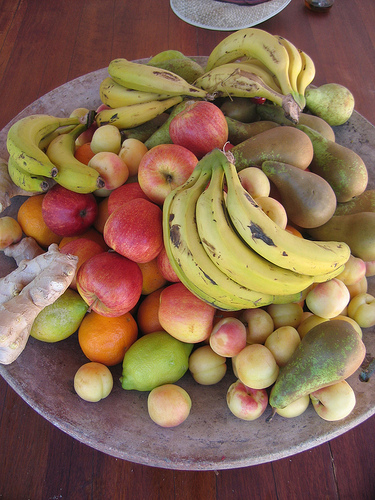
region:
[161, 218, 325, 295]
the bananass are yellow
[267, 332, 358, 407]
the pears is green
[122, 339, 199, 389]
the lemon is green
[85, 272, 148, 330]
the apple is red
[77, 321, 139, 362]
the orange is orange in color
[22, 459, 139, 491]
the table is wooden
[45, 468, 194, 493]
the table is brown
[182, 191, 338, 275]
the bananas are ripe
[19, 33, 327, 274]
there are 4 banches of bananas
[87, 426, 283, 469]
the trey is grey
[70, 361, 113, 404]
a pale yellow peach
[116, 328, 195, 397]
a pale green lime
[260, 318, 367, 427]
a green and brown mottled pear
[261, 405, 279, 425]
the brown stem of a pear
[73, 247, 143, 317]
a ripe red apple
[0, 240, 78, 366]
a tan ginger root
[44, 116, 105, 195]
a yellow ripe banana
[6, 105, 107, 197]
a bunch of bananas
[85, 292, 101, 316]
the stem of an apple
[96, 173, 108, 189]
the end of a banan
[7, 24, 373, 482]
Fruits in a bowl.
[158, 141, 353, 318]
Handle of bananas on top.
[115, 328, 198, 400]
Lemon is green.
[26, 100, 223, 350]
Red apples between handle of bananas.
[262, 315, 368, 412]
Pear is green and brown.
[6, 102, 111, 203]
Three bananas in a handle.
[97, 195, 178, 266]
Red apple next to bananas.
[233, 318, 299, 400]
White peaches next to pear.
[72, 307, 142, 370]
Orange below apple.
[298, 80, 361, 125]
Pear on border of plate.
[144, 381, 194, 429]
a pale yellow peach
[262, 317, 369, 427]
a mottled green and brown pear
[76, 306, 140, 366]
a round orange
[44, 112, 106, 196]
a yellow banana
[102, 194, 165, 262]
a ripe red apple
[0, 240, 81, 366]
a ginger root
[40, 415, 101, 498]
a brown wooden floor board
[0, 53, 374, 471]
a pale brown bowl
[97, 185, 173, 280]
the apple is red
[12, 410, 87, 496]
the table is brown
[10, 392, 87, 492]
the table is made of wood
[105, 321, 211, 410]
the lemon is green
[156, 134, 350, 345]
the banana is yellow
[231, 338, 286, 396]
the pear is yellow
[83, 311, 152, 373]
the fruit is orange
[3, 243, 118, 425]
the ginger is deformed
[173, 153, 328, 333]
the banana has bruises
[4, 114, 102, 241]
the banana is green